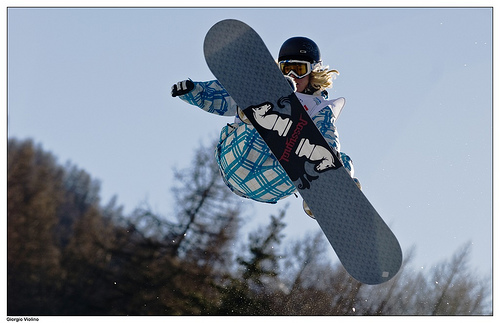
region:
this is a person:
[168, 13, 375, 221]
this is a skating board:
[198, 13, 407, 286]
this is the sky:
[354, 17, 489, 176]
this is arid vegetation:
[12, 147, 70, 304]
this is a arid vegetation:
[157, 213, 340, 315]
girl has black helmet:
[285, 27, 325, 69]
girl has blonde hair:
[315, 38, 342, 96]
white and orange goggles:
[270, 44, 317, 86]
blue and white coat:
[210, 68, 350, 178]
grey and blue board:
[233, 49, 440, 282]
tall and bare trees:
[377, 239, 469, 321]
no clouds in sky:
[360, 13, 436, 119]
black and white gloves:
[154, 82, 186, 104]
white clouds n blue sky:
[30, 39, 72, 73]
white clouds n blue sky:
[415, 65, 470, 119]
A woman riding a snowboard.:
[169, 19, 405, 286]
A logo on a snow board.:
[237, 93, 342, 188]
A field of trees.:
[6, 136, 493, 318]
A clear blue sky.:
[0, 10, 493, 310]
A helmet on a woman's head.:
[278, 36, 325, 64]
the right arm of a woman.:
[169, 77, 240, 119]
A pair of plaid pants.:
[211, 118, 294, 205]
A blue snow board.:
[200, 20, 404, 284]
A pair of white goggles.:
[278, 50, 318, 83]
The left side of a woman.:
[295, 88, 354, 183]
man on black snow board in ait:
[173, 13, 413, 293]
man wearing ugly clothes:
[191, 35, 336, 164]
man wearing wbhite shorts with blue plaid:
[211, 105, 302, 193]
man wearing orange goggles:
[276, 58, 313, 78]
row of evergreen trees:
[151, 184, 493, 304]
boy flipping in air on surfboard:
[291, 93, 319, 120]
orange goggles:
[271, 50, 321, 82]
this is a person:
[160, 13, 406, 288]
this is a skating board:
[202, 15, 412, 300]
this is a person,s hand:
[170, 68, 262, 126]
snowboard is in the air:
[200, 18, 407, 282]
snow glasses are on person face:
[276, 55, 312, 78]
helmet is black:
[276, 32, 321, 63]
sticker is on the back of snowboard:
[241, 91, 343, 191]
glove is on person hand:
[171, 77, 196, 96]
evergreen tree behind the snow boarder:
[161, 154, 223, 270]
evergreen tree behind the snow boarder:
[186, 182, 238, 290]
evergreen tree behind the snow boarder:
[217, 200, 292, 306]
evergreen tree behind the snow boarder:
[266, 230, 321, 310]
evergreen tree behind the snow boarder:
[425, 242, 473, 318]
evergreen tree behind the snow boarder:
[370, 245, 416, 313]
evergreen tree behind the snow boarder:
[13, 168, 63, 248]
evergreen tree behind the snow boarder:
[0, 130, 40, 195]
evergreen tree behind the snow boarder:
[21, 172, 109, 277]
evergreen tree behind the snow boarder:
[88, 213, 170, 312]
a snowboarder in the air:
[149, 15, 439, 291]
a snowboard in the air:
[187, 17, 417, 291]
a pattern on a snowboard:
[245, 93, 345, 194]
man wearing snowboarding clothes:
[149, 22, 376, 212]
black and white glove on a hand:
[162, 65, 205, 100]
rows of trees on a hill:
[9, 106, 487, 309]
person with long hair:
[262, 23, 358, 150]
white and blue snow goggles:
[276, 53, 322, 80]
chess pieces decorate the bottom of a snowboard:
[245, 100, 335, 170]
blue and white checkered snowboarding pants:
[213, 114, 355, 206]